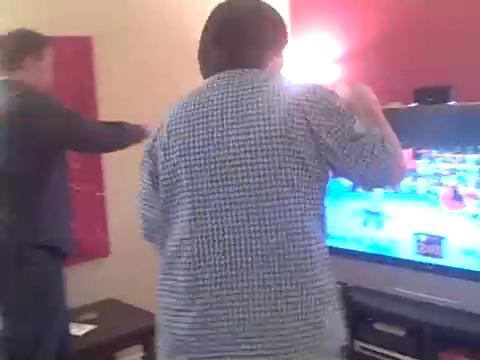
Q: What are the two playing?
A: Wii.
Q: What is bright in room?
A: Light.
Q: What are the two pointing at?
A: Tv.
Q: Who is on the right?
A: A lady.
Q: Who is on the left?
A: A man.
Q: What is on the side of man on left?
A: End table.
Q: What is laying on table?
A: Paper.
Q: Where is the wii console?
A: Under tv.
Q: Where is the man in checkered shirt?
A: Front of tv.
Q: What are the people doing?
A: Standing.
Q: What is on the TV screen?
A: A game.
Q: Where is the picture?
A: On the wall.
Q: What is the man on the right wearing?
A: A black and white shirt.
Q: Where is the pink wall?
A: Behind the TV.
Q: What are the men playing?
A: Video game.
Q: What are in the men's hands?
A: Game remotes.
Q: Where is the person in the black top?
A: On the left.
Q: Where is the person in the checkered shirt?
A: On the right.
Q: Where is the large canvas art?
A: On the wall.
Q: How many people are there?
A: Two.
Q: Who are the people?
A: Men.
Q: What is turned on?
A: Lights.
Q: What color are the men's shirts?
A: Navy.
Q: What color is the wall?
A: Red.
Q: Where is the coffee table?
A: To the left.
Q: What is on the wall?
A: A painting.